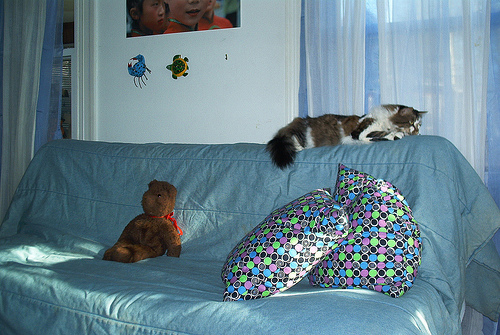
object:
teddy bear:
[102, 179, 182, 262]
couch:
[0, 135, 498, 335]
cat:
[265, 103, 428, 170]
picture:
[124, 0, 243, 39]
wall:
[99, 1, 297, 147]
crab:
[127, 53, 152, 89]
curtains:
[305, 0, 492, 183]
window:
[299, 0, 500, 195]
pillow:
[220, 186, 350, 300]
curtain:
[34, 0, 68, 154]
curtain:
[0, 0, 47, 222]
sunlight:
[0, 243, 92, 267]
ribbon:
[148, 211, 183, 235]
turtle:
[165, 54, 189, 80]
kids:
[126, 0, 239, 38]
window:
[44, 0, 102, 142]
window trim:
[74, 0, 95, 140]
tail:
[265, 119, 298, 169]